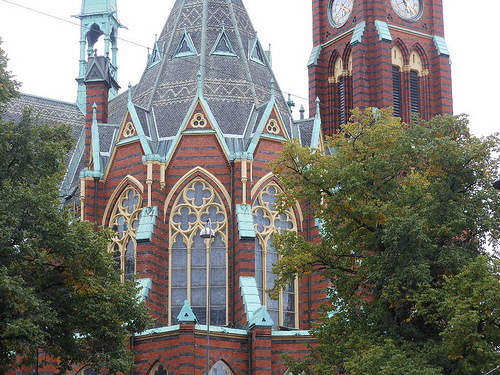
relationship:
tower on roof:
[306, 10, 469, 150] [49, 103, 326, 148]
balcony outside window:
[138, 307, 307, 352] [156, 166, 230, 323]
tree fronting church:
[284, 108, 498, 364] [16, 4, 310, 375]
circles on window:
[176, 178, 222, 230] [156, 166, 230, 323]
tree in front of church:
[284, 108, 498, 364] [16, 4, 310, 375]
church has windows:
[16, 4, 310, 375] [98, 166, 312, 338]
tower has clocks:
[306, 10, 469, 150] [322, 1, 431, 28]